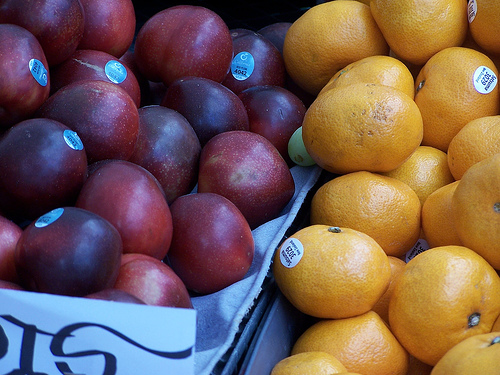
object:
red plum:
[37, 80, 140, 162]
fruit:
[235, 81, 309, 155]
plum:
[9, 207, 124, 295]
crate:
[0, 144, 322, 374]